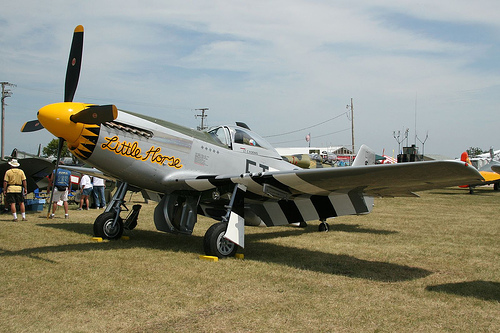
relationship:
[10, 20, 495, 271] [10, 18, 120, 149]
airplane has propellers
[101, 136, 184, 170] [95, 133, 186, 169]
cursive in cursive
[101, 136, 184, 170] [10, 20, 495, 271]
cursive on plane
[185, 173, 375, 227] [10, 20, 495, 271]
stripe on airplane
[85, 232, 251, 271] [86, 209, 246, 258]
blocks are by tire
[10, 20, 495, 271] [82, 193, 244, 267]
airplane has wheels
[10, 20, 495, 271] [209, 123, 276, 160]
airplane has windshield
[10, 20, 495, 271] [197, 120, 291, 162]
airplane has cockpit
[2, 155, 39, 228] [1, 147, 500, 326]
man standing in grass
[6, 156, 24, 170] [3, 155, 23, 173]
hat on top of man's head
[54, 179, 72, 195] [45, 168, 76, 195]
bag resting on man's back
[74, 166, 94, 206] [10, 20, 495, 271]
women crouching behind plane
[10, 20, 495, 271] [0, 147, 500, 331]
plane on top of ground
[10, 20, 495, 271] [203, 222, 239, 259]
plane has tire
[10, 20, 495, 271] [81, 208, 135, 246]
plane has wheel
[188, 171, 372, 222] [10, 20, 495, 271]
stripe painted on plane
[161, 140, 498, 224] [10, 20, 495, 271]
wing of plane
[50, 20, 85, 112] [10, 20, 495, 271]
blade of plane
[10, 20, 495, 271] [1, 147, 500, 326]
plane on top of grass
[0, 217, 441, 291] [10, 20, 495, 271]
shadow of plane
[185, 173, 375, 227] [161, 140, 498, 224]
stripe on wing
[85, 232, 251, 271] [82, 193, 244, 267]
blocks underneath wheels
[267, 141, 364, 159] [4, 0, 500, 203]
roof in background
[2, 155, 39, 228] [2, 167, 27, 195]
man has shirt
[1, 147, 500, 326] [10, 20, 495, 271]
grass underneath plane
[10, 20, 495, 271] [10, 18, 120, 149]
plane has propellers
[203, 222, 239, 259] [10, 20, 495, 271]
tire of plane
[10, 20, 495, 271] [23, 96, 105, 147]
plane has nose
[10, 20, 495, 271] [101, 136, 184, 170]
plane has cursive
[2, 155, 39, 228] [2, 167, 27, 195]
man wearing shirt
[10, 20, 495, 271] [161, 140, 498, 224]
plane has wing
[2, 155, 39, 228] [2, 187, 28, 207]
man wearing shorts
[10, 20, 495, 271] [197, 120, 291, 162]
plane has cockpit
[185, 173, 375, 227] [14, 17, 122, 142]
stripe on propeller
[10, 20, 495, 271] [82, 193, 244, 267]
plane has wheels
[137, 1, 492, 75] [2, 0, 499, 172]
clouds are in sky